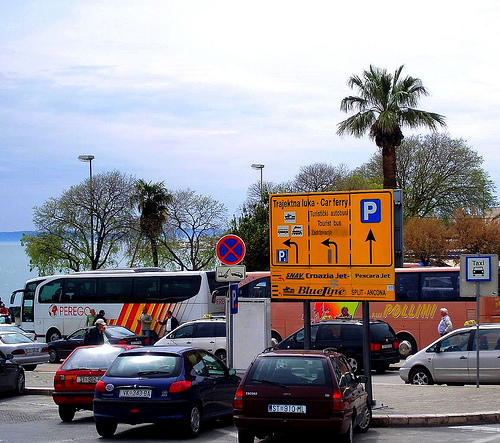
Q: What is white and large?
A: Perego bus.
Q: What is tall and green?
A: Palm tree.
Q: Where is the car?
A: Parking lot.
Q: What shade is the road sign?
A: Yellow.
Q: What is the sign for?
A: Taxis.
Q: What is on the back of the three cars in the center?
A: License plates.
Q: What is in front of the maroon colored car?
A: A sign.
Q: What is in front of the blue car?
A: A no parking sign.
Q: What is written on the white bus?
A: Perego.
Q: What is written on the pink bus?
A: Pollini.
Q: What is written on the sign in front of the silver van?
A: Taxi.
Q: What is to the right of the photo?
A: Water.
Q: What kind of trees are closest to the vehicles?
A: Palm trees.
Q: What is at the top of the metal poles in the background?
A: Lights.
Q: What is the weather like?
A: Cloudy.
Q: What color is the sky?
A: Blue.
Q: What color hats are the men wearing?
A: White.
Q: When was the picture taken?
A: During the day.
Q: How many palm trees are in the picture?
A: Two.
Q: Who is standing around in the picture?
A: People.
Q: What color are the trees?
A: Green and brown.